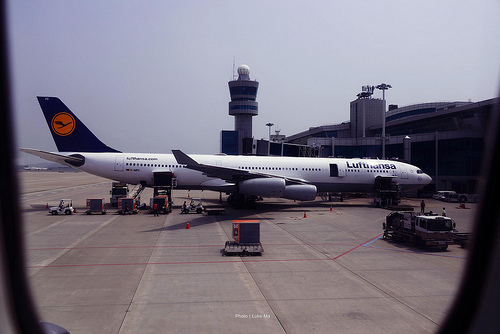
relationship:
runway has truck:
[18, 171, 476, 333] [50, 206, 77, 220]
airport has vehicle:
[344, 65, 495, 163] [383, 209, 452, 264]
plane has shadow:
[45, 89, 451, 211] [168, 212, 206, 230]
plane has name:
[45, 89, 451, 211] [342, 154, 393, 172]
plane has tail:
[45, 89, 451, 211] [32, 106, 99, 160]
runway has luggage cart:
[18, 171, 476, 333] [114, 198, 181, 216]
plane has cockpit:
[45, 89, 451, 211] [395, 158, 450, 200]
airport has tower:
[344, 65, 495, 163] [226, 56, 253, 160]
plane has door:
[45, 89, 451, 211] [323, 160, 348, 187]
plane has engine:
[45, 89, 451, 211] [230, 175, 293, 203]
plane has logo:
[45, 89, 451, 211] [51, 119, 82, 136]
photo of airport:
[10, 5, 496, 313] [344, 65, 495, 163]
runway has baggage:
[100, 237, 253, 322] [159, 177, 167, 192]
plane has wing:
[45, 89, 451, 211] [173, 144, 241, 199]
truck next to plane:
[50, 206, 77, 220] [45, 89, 451, 211]